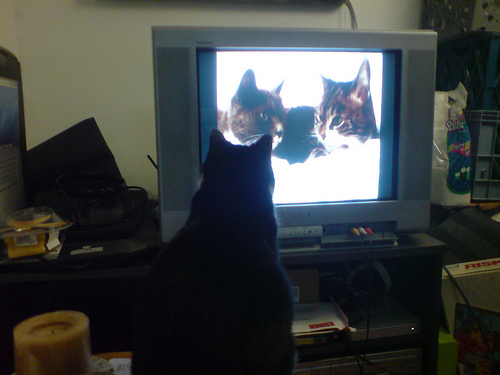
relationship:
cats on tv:
[201, 49, 390, 198] [152, 25, 431, 237]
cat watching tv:
[134, 127, 301, 373] [152, 25, 431, 237]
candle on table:
[6, 309, 99, 373] [1, 340, 272, 374]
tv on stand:
[152, 25, 431, 237] [5, 234, 447, 374]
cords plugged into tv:
[338, 219, 395, 304] [152, 25, 431, 237]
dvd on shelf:
[1, 210, 78, 263] [9, 219, 452, 281]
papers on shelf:
[282, 293, 357, 341] [273, 307, 441, 342]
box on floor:
[432, 244, 499, 326] [416, 309, 500, 373]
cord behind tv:
[140, 131, 160, 179] [152, 25, 431, 237]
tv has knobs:
[152, 25, 431, 237] [275, 221, 324, 247]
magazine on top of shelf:
[282, 293, 357, 341] [9, 219, 452, 281]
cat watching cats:
[134, 127, 301, 373] [201, 49, 390, 198]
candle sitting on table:
[6, 309, 99, 373] [1, 340, 272, 374]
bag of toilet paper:
[426, 84, 478, 211] [436, 110, 467, 161]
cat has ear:
[134, 127, 301, 373] [202, 131, 231, 153]